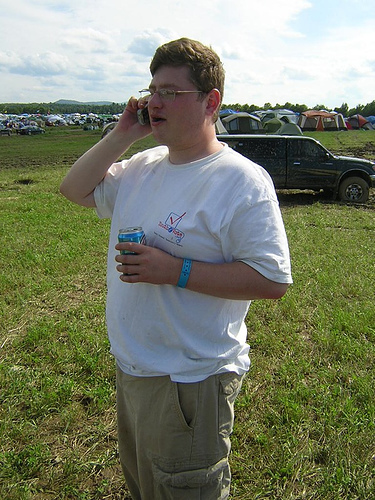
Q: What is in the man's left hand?
A: Can.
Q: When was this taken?
A: Daytime.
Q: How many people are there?
A: 1.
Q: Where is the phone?
A: Man's hand.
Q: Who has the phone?
A: Man.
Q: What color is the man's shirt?
A: White.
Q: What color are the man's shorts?
A: Tan.